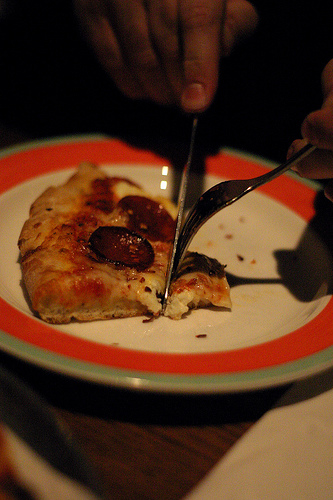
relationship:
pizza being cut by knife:
[18, 160, 232, 324] [145, 95, 208, 317]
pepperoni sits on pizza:
[85, 226, 153, 271] [17, 162, 231, 323]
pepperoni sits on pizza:
[107, 187, 178, 250] [9, 153, 243, 325]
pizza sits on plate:
[21, 159, 244, 353] [9, 138, 322, 424]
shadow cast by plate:
[1, 351, 332, 429] [1, 133, 332, 393]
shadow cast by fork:
[224, 188, 332, 300] [169, 143, 317, 281]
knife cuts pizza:
[150, 17, 229, 316] [9, 153, 243, 325]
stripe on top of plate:
[0, 295, 332, 373] [1, 133, 332, 393]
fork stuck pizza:
[126, 181, 251, 268] [23, 153, 238, 329]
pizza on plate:
[18, 160, 232, 324] [1, 133, 332, 393]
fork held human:
[170, 141, 314, 278] [80, 4, 319, 168]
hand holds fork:
[67, 12, 272, 114] [141, 130, 306, 257]